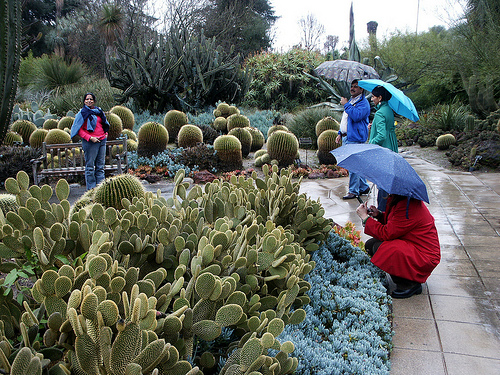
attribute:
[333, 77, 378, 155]
man — display, standing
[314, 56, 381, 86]
umbrella — grey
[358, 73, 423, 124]
umbrella — blue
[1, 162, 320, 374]
plants — short, green, wide, thick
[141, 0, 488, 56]
sky — cloudy, clear, bright, white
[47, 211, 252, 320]
catus — garden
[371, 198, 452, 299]
coat — red, in color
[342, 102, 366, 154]
coat — blue, in color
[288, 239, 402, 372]
flowers — in color, light blue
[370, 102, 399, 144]
coat — tourquiose, in color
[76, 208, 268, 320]
catus — in color, light green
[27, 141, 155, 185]
bench — grey brown, color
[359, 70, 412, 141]
umbrella — tourquious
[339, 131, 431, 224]
umbrella — blue, in color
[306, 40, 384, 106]
umbrella — in color, grey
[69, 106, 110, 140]
coat — light, dark, blue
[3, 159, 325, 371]
cactus — small